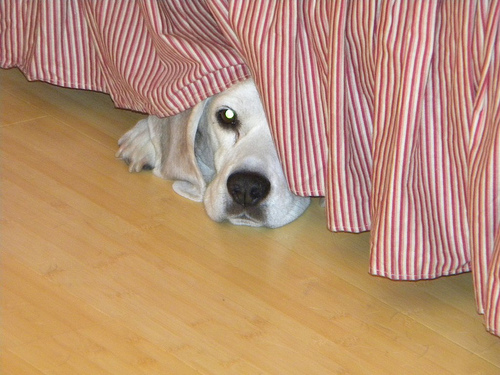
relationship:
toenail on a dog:
[122, 160, 147, 178] [108, 69, 311, 225]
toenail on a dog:
[110, 136, 128, 157] [115, 76, 310, 227]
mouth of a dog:
[226, 204, 273, 233] [115, 67, 304, 230]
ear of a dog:
[148, 101, 205, 203] [102, 71, 344, 261]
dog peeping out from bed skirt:
[115, 76, 310, 227] [0, 0, 498, 335]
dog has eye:
[115, 76, 310, 227] [213, 105, 237, 132]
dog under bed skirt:
[115, 76, 310, 227] [0, 0, 499, 336]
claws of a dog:
[115, 120, 155, 173] [115, 76, 310, 227]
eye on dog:
[214, 106, 243, 127] [115, 76, 310, 227]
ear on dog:
[148, 88, 211, 207] [115, 76, 310, 227]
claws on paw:
[116, 122, 143, 173] [115, 115, 159, 174]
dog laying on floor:
[115, 76, 310, 227] [0, 63, 499, 373]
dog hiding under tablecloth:
[115, 76, 310, 227] [0, 0, 500, 338]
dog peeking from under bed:
[108, 69, 311, 225] [3, 0, 498, 335]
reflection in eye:
[223, 104, 233, 119] [214, 106, 243, 127]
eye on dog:
[214, 106, 243, 127] [108, 69, 311, 225]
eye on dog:
[216, 104, 246, 135] [115, 76, 310, 227]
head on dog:
[193, 79, 308, 234] [108, 69, 311, 225]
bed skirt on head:
[0, 0, 498, 335] [193, 79, 308, 234]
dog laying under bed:
[115, 76, 310, 227] [3, 0, 498, 335]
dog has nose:
[115, 76, 310, 227] [224, 165, 277, 208]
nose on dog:
[223, 169, 275, 209] [115, 76, 310, 227]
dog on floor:
[115, 76, 310, 227] [0, 63, 499, 373]